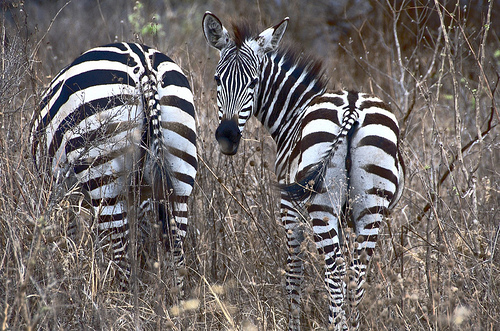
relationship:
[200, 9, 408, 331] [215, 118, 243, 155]
zebra has nose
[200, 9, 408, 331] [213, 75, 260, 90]
zebra has eyes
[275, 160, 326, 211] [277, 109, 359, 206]
hair on tip of tail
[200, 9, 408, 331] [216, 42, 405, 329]
zebra has stripes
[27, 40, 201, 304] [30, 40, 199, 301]
zebra has stripes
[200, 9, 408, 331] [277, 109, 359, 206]
zebra has tail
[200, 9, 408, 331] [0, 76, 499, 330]
zebra standing in grass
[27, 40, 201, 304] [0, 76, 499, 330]
zebra standing in grass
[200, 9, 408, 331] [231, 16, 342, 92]
zebra has mane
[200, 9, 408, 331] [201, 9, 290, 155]
zebra has head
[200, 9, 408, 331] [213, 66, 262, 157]
zebra has face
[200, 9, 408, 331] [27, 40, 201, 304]
zebra to right of zebra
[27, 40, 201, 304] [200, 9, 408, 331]
zebra to left of zebra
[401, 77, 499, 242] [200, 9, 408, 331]
twig to right of zebra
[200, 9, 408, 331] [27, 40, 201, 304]
zebra together with zebra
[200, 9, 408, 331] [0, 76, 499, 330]
zebra in grass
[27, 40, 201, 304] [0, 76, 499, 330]
zebra in grass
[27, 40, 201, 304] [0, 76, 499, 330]
zebra eating grass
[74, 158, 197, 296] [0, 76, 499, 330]
legs are behind grass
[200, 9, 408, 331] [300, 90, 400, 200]
zebra has rear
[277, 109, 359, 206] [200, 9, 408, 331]
tail on back of zebra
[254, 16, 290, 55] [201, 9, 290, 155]
ear on head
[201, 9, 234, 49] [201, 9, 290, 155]
ear on head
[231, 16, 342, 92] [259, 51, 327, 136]
mane on neck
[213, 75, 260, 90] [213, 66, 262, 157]
eyes are on face